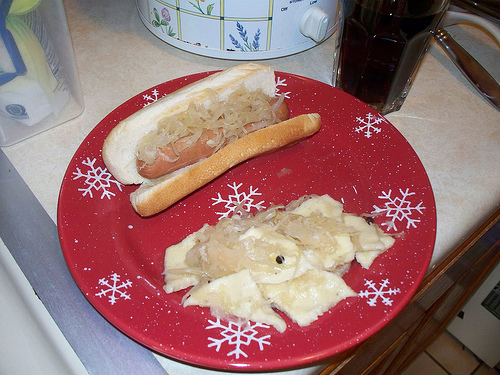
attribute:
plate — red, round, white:
[28, 58, 441, 368]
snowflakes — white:
[369, 181, 432, 241]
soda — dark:
[361, 8, 417, 75]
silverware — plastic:
[17, 9, 72, 102]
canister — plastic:
[2, 5, 87, 155]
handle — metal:
[459, 58, 499, 107]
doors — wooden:
[407, 293, 467, 356]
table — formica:
[13, 13, 499, 340]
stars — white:
[87, 165, 110, 193]